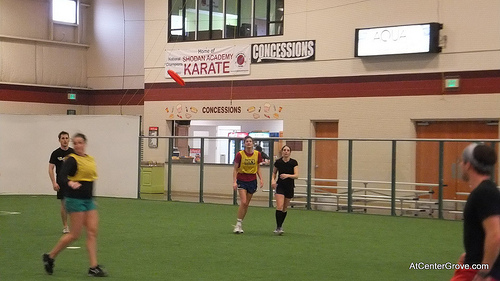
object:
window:
[252, 0, 271, 39]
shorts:
[59, 196, 98, 213]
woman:
[228, 135, 266, 235]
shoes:
[271, 227, 286, 235]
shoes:
[231, 225, 245, 234]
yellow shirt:
[66, 151, 99, 183]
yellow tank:
[235, 149, 261, 174]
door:
[311, 119, 339, 195]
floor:
[0, 194, 499, 281]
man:
[448, 139, 499, 280]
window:
[199, 138, 229, 165]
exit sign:
[65, 92, 77, 101]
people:
[41, 132, 109, 280]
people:
[267, 145, 299, 235]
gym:
[0, 0, 499, 280]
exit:
[442, 79, 460, 89]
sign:
[162, 44, 254, 80]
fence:
[138, 133, 499, 221]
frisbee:
[166, 68, 186, 88]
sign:
[248, 37, 318, 65]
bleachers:
[253, 175, 468, 222]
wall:
[87, 0, 499, 201]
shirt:
[457, 177, 499, 280]